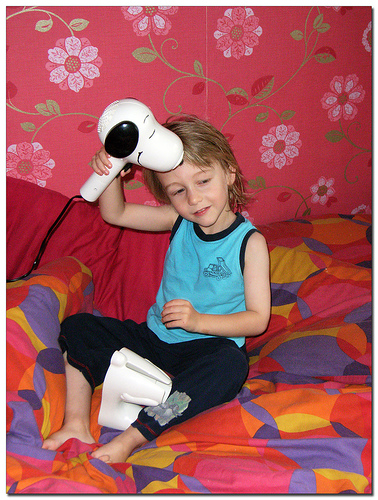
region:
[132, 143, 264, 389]
this is a child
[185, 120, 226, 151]
this is the hair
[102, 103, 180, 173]
this is a blow dry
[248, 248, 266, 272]
the child is light skinned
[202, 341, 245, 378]
this is the knee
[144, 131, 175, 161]
the blow dry is white in color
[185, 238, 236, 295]
this is a vest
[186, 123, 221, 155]
the hair is wet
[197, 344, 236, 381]
the pyjama is black in color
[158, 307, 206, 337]
these are the fingers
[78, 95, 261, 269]
Young girl holding a hair dryer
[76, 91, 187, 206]
Hair dryer shaped like Snoopy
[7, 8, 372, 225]
Wallpaper on the wall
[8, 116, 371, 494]
Young girl sitting on a bed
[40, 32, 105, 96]
Flower design on the wallpaper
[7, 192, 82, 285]
Black wire of the hairdryer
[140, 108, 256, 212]
Blonde wet hair on girl's head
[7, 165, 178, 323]
A red colored pillow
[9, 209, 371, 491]
A colorful comforter on the bed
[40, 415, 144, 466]
A pair of bare feet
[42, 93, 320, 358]
a girl with a blow dryer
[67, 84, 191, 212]
the blow dryer looks like snoopy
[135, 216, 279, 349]
the girl is wearing a blue shirt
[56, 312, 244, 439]
the girl has on blue pants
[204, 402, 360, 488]
this blanket is colorful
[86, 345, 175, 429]
this is a hair dryer holder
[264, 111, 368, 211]
a pink pillow in the background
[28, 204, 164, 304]
dark pink bedding on the bed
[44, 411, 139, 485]
the girl is not wearing shoes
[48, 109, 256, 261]
the is enjoying her hair dryer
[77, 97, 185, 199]
white and black hair drier shaped like snoppy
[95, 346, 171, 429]
white plastic hair drier attachment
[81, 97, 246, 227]
boy holding drier with wet hair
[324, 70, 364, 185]
floral patterns on back wall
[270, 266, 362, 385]
multi color bed spread by boy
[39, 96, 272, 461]
boy wearing blue shirt drying hair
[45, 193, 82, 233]
black power cord of white dryer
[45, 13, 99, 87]
white and pink flowers with green stems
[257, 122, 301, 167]
pink flowers painted on wall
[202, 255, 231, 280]
black truck on boys blue shirt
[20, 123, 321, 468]
a child sitting on a bed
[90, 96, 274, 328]
a child holding a hair dryer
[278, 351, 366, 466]
colorful patterned comforter on the bed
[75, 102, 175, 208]
a hair dryer in the shape of Snoopy's head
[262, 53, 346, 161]
pink patterned walls of the room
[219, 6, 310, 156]
flowers on the wall of the room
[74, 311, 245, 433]
the child's black pants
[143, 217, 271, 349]
the child's blue sleeveless shirt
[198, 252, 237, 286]
black logo on the child's blue shirt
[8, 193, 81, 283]
black power cord of the hair dryer